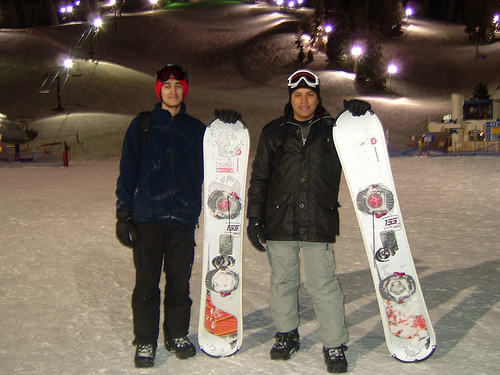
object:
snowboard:
[198, 114, 250, 358]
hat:
[153, 65, 188, 104]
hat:
[287, 70, 324, 101]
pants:
[267, 237, 348, 347]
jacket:
[115, 103, 208, 222]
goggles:
[286, 70, 323, 90]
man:
[244, 67, 374, 373]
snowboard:
[331, 109, 439, 362]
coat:
[247, 102, 344, 243]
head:
[155, 65, 190, 108]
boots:
[133, 339, 158, 367]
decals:
[207, 188, 243, 218]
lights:
[89, 16, 107, 26]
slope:
[58, 27, 103, 97]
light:
[347, 42, 368, 61]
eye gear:
[154, 65, 189, 79]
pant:
[128, 231, 194, 340]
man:
[115, 62, 242, 367]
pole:
[352, 55, 358, 72]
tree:
[352, 32, 390, 95]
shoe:
[270, 327, 300, 360]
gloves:
[247, 216, 272, 252]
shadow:
[345, 260, 499, 371]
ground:
[0, 155, 499, 374]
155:
[226, 224, 240, 232]